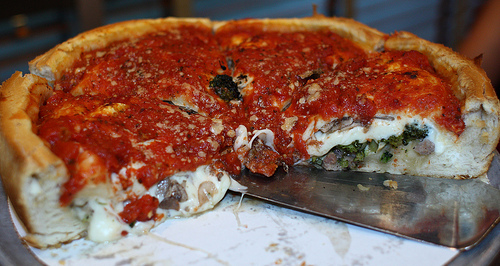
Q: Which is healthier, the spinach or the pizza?
A: The spinach is healthier than the pizza.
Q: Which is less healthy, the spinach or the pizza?
A: The pizza is less healthy than the spinach.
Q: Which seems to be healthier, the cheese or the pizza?
A: The cheese is healthier than the pizza.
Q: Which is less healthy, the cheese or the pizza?
A: The pizza is less healthy than the cheese.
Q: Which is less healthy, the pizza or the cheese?
A: The pizza is less healthy than the cheese.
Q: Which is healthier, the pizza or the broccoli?
A: The broccoli is healthier than the pizza.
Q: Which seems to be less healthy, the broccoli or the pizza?
A: The pizza is less healthy than the broccoli.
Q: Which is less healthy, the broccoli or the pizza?
A: The pizza is less healthy than the broccoli.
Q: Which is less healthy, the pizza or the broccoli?
A: The pizza is less healthy than the broccoli.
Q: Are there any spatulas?
A: Yes, there is a spatula.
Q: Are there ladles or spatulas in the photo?
A: Yes, there is a spatula.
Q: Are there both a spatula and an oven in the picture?
A: No, there is a spatula but no ovens.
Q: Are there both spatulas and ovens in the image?
A: No, there is a spatula but no ovens.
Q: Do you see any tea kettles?
A: No, there are no tea kettles.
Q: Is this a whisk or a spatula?
A: This is a spatula.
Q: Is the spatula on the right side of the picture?
A: Yes, the spatula is on the right of the image.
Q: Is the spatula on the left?
A: No, the spatula is on the right of the image.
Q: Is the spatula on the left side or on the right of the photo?
A: The spatula is on the right of the image.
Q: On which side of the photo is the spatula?
A: The spatula is on the right of the image.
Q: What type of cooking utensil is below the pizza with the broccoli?
A: The cooking utensil is a spatula.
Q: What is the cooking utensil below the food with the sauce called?
A: The cooking utensil is a spatula.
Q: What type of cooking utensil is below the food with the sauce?
A: The cooking utensil is a spatula.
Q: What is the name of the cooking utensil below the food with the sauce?
A: The cooking utensil is a spatula.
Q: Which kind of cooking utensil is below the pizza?
A: The cooking utensil is a spatula.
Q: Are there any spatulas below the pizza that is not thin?
A: Yes, there is a spatula below the pizza.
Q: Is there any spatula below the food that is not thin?
A: Yes, there is a spatula below the pizza.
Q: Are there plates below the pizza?
A: No, there is a spatula below the pizza.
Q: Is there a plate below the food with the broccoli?
A: No, there is a spatula below the pizza.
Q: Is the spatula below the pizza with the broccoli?
A: Yes, the spatula is below the pizza.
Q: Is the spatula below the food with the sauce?
A: Yes, the spatula is below the pizza.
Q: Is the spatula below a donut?
A: No, the spatula is below the pizza.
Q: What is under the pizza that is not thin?
A: The spatula is under the pizza.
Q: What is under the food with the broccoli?
A: The spatula is under the pizza.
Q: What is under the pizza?
A: The spatula is under the pizza.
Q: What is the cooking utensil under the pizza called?
A: The cooking utensil is a spatula.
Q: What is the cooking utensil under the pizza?
A: The cooking utensil is a spatula.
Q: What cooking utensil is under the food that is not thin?
A: The cooking utensil is a spatula.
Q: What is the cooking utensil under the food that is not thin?
A: The cooking utensil is a spatula.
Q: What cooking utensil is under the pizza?
A: The cooking utensil is a spatula.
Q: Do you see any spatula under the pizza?
A: Yes, there is a spatula under the pizza.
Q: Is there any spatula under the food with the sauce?
A: Yes, there is a spatula under the pizza.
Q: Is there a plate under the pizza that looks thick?
A: No, there is a spatula under the pizza.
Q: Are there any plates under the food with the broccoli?
A: No, there is a spatula under the pizza.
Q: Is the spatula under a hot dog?
A: No, the spatula is under a pizza.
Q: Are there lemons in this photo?
A: No, there are no lemons.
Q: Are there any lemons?
A: No, there are no lemons.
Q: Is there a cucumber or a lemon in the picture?
A: No, there are no lemons or cucumbers.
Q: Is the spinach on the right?
A: Yes, the spinach is on the right of the image.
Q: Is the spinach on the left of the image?
A: No, the spinach is on the right of the image.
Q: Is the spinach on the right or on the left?
A: The spinach is on the right of the image.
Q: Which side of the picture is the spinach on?
A: The spinach is on the right of the image.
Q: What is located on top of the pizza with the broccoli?
A: The sauce is on top of the pizza.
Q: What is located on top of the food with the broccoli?
A: The sauce is on top of the pizza.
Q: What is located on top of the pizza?
A: The sauce is on top of the pizza.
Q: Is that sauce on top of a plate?
A: No, the sauce is on top of the pizza.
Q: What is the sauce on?
A: The sauce is on the pizza.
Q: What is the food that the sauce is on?
A: The food is a pizza.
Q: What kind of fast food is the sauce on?
A: The sauce is on the pizza.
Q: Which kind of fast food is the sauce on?
A: The sauce is on the pizza.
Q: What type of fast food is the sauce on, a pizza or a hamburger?
A: The sauce is on a pizza.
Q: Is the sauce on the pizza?
A: Yes, the sauce is on the pizza.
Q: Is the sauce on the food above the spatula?
A: Yes, the sauce is on the pizza.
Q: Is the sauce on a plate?
A: No, the sauce is on the pizza.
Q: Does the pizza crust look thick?
A: Yes, the crust is thick.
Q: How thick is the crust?
A: The crust is thick.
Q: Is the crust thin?
A: No, the crust is thick.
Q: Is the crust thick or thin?
A: The crust is thick.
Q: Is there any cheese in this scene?
A: Yes, there is cheese.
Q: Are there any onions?
A: No, there are no onions.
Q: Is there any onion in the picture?
A: No, there are no onions.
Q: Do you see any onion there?
A: No, there are no onions.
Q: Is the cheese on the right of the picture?
A: Yes, the cheese is on the right of the image.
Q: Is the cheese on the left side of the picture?
A: No, the cheese is on the right of the image.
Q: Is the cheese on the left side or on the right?
A: The cheese is on the right of the image.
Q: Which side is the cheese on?
A: The cheese is on the right of the image.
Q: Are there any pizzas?
A: Yes, there is a pizza.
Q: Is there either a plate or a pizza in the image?
A: Yes, there is a pizza.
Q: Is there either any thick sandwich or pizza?
A: Yes, there is a thick pizza.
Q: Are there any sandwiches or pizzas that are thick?
A: Yes, the pizza is thick.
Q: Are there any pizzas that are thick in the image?
A: Yes, there is a thick pizza.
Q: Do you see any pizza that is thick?
A: Yes, there is a pizza that is thick.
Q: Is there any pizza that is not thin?
A: Yes, there is a thick pizza.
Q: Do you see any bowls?
A: No, there are no bowls.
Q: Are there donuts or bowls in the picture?
A: No, there are no bowls or donuts.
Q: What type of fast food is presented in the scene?
A: The fast food is a pizza.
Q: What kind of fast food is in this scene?
A: The fast food is a pizza.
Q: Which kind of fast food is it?
A: The food is a pizza.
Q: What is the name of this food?
A: That is a pizza.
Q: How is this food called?
A: That is a pizza.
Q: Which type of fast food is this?
A: That is a pizza.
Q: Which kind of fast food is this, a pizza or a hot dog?
A: That is a pizza.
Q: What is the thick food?
A: The food is a pizza.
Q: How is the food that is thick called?
A: The food is a pizza.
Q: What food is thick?
A: The food is a pizza.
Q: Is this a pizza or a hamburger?
A: This is a pizza.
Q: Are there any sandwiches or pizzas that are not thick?
A: No, there is a pizza but it is thick.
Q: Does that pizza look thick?
A: Yes, the pizza is thick.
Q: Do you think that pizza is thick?
A: Yes, the pizza is thick.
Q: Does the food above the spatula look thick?
A: Yes, the pizza is thick.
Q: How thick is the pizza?
A: The pizza is thick.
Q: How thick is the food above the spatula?
A: The pizza is thick.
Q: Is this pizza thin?
A: No, the pizza is thick.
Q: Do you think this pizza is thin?
A: No, the pizza is thick.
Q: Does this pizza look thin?
A: No, the pizza is thick.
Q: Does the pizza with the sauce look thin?
A: No, the pizza is thick.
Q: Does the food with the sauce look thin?
A: No, the pizza is thick.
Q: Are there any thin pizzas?
A: No, there is a pizza but it is thick.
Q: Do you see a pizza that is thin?
A: No, there is a pizza but it is thick.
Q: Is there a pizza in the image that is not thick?
A: No, there is a pizza but it is thick.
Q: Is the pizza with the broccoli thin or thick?
A: The pizza is thick.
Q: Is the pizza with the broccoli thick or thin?
A: The pizza is thick.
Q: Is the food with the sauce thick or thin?
A: The pizza is thick.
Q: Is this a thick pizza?
A: Yes, this is a thick pizza.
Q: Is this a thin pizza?
A: No, this is a thick pizza.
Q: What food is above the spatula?
A: The food is a pizza.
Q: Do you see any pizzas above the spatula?
A: Yes, there is a pizza above the spatula.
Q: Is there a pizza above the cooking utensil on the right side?
A: Yes, there is a pizza above the spatula.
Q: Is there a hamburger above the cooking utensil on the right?
A: No, there is a pizza above the spatula.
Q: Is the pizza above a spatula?
A: Yes, the pizza is above a spatula.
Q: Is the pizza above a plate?
A: No, the pizza is above a spatula.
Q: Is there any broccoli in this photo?
A: Yes, there is broccoli.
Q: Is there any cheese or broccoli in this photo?
A: Yes, there is broccoli.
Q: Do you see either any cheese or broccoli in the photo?
A: Yes, there is broccoli.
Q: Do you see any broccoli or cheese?
A: Yes, there is broccoli.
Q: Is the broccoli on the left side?
A: No, the broccoli is on the right of the image.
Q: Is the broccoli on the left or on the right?
A: The broccoli is on the right of the image.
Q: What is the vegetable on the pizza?
A: The vegetable is broccoli.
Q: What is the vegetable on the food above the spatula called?
A: The vegetable is broccoli.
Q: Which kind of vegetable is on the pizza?
A: The vegetable is broccoli.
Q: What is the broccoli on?
A: The broccoli is on the pizza.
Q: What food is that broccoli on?
A: The broccoli is on the pizza.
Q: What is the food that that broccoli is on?
A: The food is a pizza.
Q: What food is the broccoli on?
A: The broccoli is on the pizza.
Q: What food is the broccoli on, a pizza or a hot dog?
A: The broccoli is on a pizza.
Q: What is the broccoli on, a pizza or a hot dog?
A: The broccoli is on a pizza.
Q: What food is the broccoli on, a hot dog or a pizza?
A: The broccoli is on a pizza.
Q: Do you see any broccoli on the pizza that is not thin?
A: Yes, there is broccoli on the pizza.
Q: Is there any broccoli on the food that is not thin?
A: Yes, there is broccoli on the pizza.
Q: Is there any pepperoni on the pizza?
A: No, there is broccoli on the pizza.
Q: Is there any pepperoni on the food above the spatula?
A: No, there is broccoli on the pizza.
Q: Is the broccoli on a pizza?
A: Yes, the broccoli is on a pizza.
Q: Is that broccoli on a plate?
A: No, the broccoli is on a pizza.